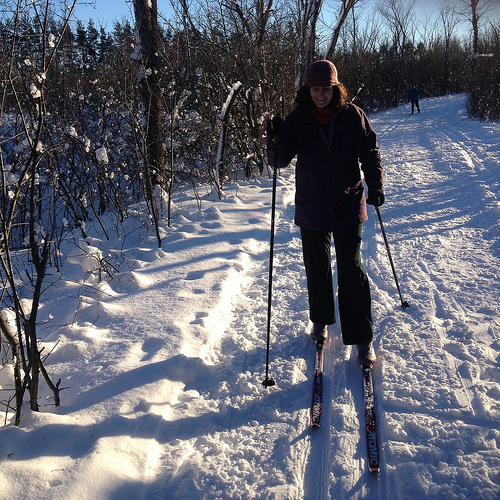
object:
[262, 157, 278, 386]
pole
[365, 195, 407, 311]
pole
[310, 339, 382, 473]
skis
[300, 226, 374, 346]
snow pants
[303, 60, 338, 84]
hat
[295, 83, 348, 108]
hair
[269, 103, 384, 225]
snow jacket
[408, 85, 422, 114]
skier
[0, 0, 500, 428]
trees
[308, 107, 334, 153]
scarf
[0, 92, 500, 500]
shadow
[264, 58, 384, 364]
trail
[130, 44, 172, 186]
trunk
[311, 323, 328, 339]
boots